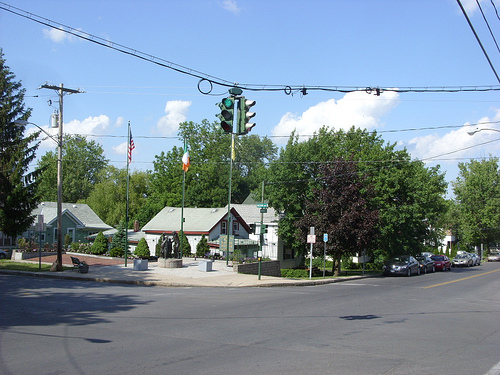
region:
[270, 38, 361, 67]
the sky is clear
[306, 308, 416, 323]
shadows on the street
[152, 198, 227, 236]
roof on the building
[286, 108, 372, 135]
cloud in the sky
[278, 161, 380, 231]
top of the tree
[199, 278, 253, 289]
curb of the sidewalk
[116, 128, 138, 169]
flag in the sky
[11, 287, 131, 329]
shadow of the trees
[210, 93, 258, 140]
traffic light on pole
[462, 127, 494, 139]
light of the streetlight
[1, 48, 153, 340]
Pine tree and its shadow in the street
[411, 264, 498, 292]
Yellow line in the street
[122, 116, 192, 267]
Two flags on poles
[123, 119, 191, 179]
The flags show there is no wind.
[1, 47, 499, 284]
A variety of different trees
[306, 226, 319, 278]
Street sign on a post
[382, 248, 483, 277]
A row of cars parked on the side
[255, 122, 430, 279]
One tree is green and one is purple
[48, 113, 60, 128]
Transformer on a telephone pole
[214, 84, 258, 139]
A traffic light hanging in the intersection.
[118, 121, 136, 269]
a flag on a pole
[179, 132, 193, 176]
a green, white, and orange flag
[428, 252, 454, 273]
a red car parked alongside a road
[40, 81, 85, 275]
a wooden utility pole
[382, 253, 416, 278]
a silver car parked alongside the road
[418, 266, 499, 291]
a yellow line painted in a road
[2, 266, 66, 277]
a sidewalk alongside a road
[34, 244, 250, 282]
a small courtyard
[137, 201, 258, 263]
a small white house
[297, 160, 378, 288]
a purplish green tree by the side of the road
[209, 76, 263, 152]
signal lights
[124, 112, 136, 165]
flag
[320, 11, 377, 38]
white clouds in blue sky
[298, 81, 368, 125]
white clouds in blue sky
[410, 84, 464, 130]
white clouds in blue sky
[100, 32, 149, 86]
white clouds in blue sky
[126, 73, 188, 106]
white clouds in blue sky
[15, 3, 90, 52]
white clouds in blue sky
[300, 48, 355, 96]
white clouds in blue sky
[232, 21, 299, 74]
white clouds in blue sky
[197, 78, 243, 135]
The stoplight is green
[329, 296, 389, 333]
Stoplight reflected on the street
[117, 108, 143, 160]
An American flag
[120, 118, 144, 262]
The flag is on a pole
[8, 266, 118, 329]
Tree shadow on the street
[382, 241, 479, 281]
Cars parked on the side of the road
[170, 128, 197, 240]
Green, white, and orange flag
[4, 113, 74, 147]
Light on wooden post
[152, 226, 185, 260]
A bronze statue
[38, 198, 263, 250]
Two houses